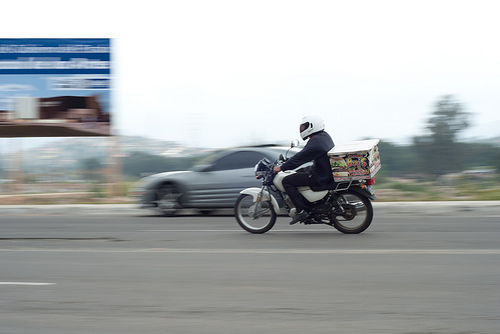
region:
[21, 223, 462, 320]
street for vehicles to travel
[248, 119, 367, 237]
person on motorized bike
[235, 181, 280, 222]
front tire on bike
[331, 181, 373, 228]
rear tire on bike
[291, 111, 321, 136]
helmet on the biker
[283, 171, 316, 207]
pants on the biker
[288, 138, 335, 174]
jacket on the biker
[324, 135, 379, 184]
basket on the biker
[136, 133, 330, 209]
vehicle on the street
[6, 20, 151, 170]
billboard on the street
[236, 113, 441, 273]
a motorcycle riding down the street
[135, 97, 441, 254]
a silver car and a motorcycle riding down the street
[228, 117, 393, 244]
a person riding a motorcycle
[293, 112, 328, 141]
a white motorcycle helmet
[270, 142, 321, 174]
the arm of a person riding a motorcycle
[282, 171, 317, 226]
the leg of a person riding a motorcycle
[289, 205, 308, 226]
the foot of a person riding a motorcycle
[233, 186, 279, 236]
the front wheel of a motorcycle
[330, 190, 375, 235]
the rear wheel of a motorcycle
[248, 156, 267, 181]
the headlight of a motorcycle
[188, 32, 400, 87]
this is the sky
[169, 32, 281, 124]
the sky is blue in color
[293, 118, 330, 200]
this is a man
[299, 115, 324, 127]
this is a helmet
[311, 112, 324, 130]
the helmet is white in color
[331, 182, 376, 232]
this is a motorbike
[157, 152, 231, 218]
this is a car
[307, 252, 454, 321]
this is the road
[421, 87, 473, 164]
this is a tree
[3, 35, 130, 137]
this is a post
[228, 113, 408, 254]
a man on amotorbike in a highway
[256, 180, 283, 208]
the motorbike is white in color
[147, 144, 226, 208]
the car is runing on a highway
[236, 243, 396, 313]
the road is terrain rough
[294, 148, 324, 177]
the jacket is dark blue in color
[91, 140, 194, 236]
the car is blurred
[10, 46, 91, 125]
the sighn post is multicolored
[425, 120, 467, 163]
the trees are green in color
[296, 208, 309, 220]
the shoes are black in color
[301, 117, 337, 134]
the helmet is white in color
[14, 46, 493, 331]
person riding motorcycle down the street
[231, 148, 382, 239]
motorcycle is white and black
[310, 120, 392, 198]
box strapped to back of bike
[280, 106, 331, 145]
person wearing white helmet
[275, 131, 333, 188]
person wearing black top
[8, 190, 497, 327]
white line drawn on road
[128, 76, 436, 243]
grey car next to motorcycle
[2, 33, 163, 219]
blue sign next to roadway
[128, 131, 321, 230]
grey car has tinted windows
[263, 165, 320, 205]
person wearing black pants